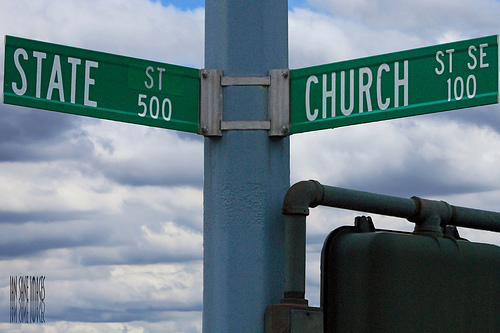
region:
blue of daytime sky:
[160, 0, 209, 13]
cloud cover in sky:
[3, 2, 498, 329]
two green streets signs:
[0, 34, 496, 136]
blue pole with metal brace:
[202, 16, 292, 331]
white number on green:
[134, 90, 174, 121]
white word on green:
[303, 58, 411, 124]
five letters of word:
[10, 47, 97, 107]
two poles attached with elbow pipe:
[280, 178, 498, 299]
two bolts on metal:
[275, 68, 292, 136]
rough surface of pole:
[217, 172, 270, 233]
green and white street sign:
[304, 37, 481, 124]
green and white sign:
[4, 29, 186, 165]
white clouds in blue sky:
[9, 129, 69, 197]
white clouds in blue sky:
[95, 143, 163, 206]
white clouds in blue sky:
[33, 188, 140, 259]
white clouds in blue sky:
[116, 191, 192, 259]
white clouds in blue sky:
[74, 248, 159, 309]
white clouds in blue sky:
[62, 13, 158, 44]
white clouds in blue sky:
[293, 13, 348, 46]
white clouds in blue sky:
[312, 135, 394, 176]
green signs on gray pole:
[0, 30, 495, 146]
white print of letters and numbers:
[2, 27, 199, 132]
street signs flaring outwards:
[5, 31, 495, 137]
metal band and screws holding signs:
[197, 65, 287, 140]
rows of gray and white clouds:
[1, 95, 196, 330]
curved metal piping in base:
[260, 175, 491, 325]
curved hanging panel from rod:
[315, 215, 495, 325]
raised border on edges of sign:
[290, 30, 495, 130]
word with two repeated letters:
[300, 55, 410, 120]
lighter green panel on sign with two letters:
[116, 50, 191, 100]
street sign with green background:
[6, 32, 202, 147]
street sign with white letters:
[1, 34, 206, 144]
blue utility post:
[195, 3, 325, 332]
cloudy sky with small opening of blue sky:
[0, 0, 495, 332]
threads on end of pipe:
[278, 285, 311, 302]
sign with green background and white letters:
[5, 32, 201, 149]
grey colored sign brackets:
[192, 65, 298, 140]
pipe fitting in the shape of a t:
[406, 189, 460, 244]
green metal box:
[320, 212, 498, 329]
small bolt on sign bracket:
[197, 69, 214, 83]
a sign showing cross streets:
[0, 13, 499, 138]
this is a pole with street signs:
[186, 11, 292, 328]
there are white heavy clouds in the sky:
[45, 126, 190, 317]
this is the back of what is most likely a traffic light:
[261, 170, 491, 330]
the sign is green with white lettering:
[12, 30, 237, 155]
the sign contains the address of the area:
[270, 21, 495, 127]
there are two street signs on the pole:
[30, 21, 490, 131]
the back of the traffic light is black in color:
[283, 179, 490, 321]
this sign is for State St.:
[7, 18, 188, 144]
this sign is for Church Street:
[289, 36, 491, 130]